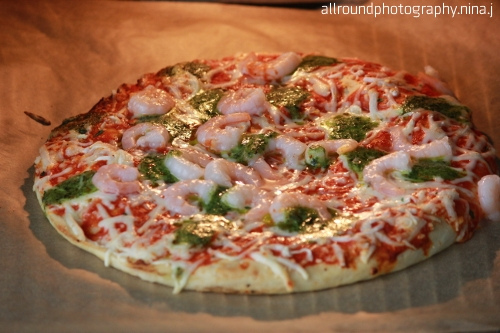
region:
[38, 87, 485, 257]
A delicious looking pizza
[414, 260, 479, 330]
A clear table surface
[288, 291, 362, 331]
A clear table surface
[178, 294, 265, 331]
A clear table surface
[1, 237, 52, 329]
A clear table surface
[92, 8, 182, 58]
A white table surface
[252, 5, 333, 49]
A white table surface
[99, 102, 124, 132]
tomato sauce on top of a pizza.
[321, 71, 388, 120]
cheese topping with sauce.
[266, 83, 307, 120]
a dark green topping.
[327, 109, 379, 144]
a green spinach topping.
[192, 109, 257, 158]
shrimps on top of the pizza.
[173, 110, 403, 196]
two toppings on a pizza shrimp and spinach.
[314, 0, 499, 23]
a picture says all round photography.nina.j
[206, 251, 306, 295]
a thick piece of crust.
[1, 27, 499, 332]
a delicious big round pizza pie.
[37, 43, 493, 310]
pizza with cheese, shrimp and basil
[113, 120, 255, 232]
pink shrimp on a pizza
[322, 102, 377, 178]
green leaves of basil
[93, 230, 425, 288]
crust of a pizza with melted cheese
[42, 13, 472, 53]
brown paper pizza is sitting on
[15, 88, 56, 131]
burnt piece of cheese on paper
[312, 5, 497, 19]
white text at the top right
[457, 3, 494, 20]
the name of photographer in white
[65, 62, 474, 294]
cheesy shrimp pizza with red sauce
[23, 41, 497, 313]
A freshly cooked pizza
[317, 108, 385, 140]
Broccoli topping a pizza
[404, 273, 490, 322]
Brown parchment paper on a rack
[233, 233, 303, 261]
Melted cheese on a pizza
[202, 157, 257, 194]
Shrimp topping a pizza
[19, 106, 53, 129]
A brown crumb on parchment paper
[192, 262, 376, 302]
Brown crust of a pizza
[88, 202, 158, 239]
An area of cheese and sauce on a pizza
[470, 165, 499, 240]
A piece of shrimp on the side of a pizza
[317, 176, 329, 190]
A piece of food.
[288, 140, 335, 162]
A piece of food.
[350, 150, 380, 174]
A piece of food.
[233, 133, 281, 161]
A piece of food.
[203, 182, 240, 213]
A piece of food.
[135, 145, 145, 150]
A piece of food.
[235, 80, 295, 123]
A piece of food.